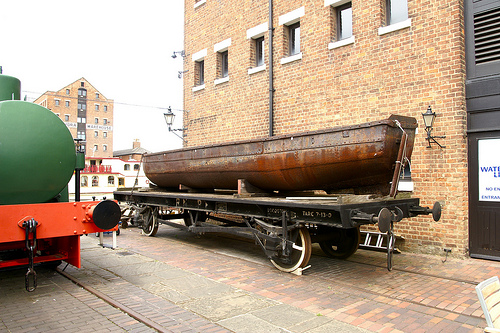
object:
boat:
[140, 113, 419, 194]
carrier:
[112, 182, 442, 274]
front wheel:
[261, 216, 312, 273]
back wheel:
[137, 203, 160, 237]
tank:
[0, 65, 87, 205]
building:
[181, 0, 469, 257]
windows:
[195, 59, 206, 87]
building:
[30, 76, 116, 159]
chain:
[21, 217, 40, 294]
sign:
[477, 138, 500, 201]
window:
[286, 19, 302, 55]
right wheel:
[182, 199, 208, 230]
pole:
[267, 0, 274, 137]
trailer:
[0, 196, 121, 293]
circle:
[90, 198, 122, 231]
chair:
[473, 275, 500, 333]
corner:
[441, 305, 500, 332]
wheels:
[314, 215, 365, 259]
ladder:
[359, 227, 406, 254]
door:
[463, 122, 500, 261]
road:
[0, 234, 499, 333]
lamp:
[420, 104, 446, 149]